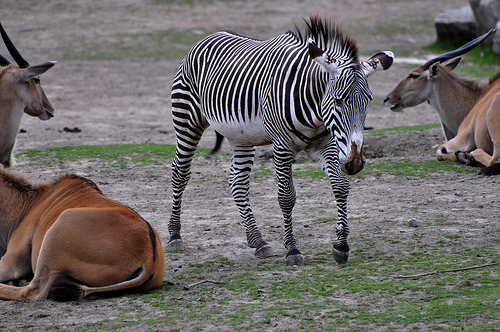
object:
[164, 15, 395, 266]
zebra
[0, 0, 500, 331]
field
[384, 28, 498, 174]
giselle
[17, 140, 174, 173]
grass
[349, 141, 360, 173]
nose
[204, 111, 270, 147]
stomach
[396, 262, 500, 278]
branch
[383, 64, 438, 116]
head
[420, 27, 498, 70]
horns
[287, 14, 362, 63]
mane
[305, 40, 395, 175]
head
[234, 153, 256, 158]
stripe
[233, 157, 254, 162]
stripe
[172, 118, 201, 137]
stripe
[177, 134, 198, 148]
stripe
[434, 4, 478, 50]
rock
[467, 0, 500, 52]
rock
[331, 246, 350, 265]
hoof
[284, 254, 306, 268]
hoof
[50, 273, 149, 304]
tail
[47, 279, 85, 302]
end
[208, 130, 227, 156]
tail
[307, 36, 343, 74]
ear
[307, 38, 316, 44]
tip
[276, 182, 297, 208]
knee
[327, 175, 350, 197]
knee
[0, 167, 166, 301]
animal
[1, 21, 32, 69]
horn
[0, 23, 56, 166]
animal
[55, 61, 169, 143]
patch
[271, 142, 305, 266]
leg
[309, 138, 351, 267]
leg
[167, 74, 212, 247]
leg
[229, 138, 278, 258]
leg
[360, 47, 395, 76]
ear